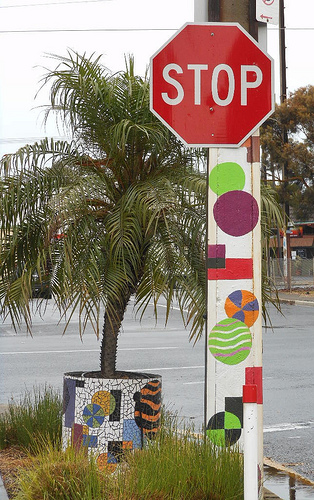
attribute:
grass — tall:
[161, 423, 198, 482]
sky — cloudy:
[121, 10, 165, 22]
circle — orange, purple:
[208, 176, 262, 239]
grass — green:
[4, 388, 253, 499]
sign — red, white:
[144, 21, 281, 152]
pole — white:
[214, 143, 265, 498]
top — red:
[148, 17, 278, 153]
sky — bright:
[96, 5, 166, 22]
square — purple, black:
[206, 243, 226, 269]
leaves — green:
[67, 58, 180, 277]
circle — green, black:
[197, 402, 264, 472]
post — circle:
[206, 147, 273, 499]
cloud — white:
[1, 0, 193, 175]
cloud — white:
[266, 0, 311, 104]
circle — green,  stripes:
[206, 308, 262, 371]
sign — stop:
[153, 20, 275, 173]